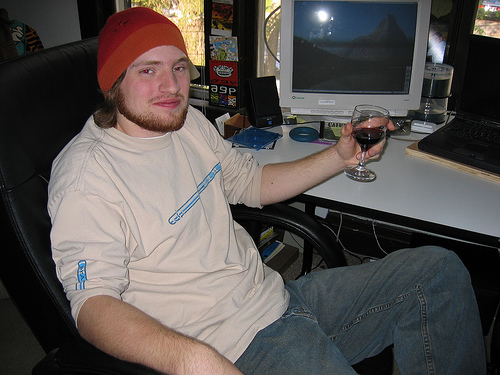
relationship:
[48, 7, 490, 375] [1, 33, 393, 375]
man sitting in chair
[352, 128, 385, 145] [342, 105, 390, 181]
wine in wine glass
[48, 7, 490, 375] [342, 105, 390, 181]
man holding wine glass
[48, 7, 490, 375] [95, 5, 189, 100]
man wearing hat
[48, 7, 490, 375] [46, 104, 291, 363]
man wearing shirt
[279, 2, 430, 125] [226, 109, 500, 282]
computer monitor on table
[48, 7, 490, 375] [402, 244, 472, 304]
man has knee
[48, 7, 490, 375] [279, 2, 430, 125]
man sitting next to computer monitor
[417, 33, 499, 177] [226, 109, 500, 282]
laptop computer on table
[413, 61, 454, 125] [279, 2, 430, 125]
stack of cds behind computer monitor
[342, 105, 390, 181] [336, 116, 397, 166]
wine glass in hand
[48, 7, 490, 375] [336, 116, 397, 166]
man has hand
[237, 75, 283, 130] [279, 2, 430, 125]
speaker next to computer monitor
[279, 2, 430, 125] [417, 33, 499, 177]
computer monitor next to laptop computer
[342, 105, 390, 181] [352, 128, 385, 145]
wine glass has wine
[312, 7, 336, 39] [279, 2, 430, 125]
reflection in computer monitor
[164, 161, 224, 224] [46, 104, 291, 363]
design on shirt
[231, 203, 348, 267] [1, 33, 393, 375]
arm rest on chair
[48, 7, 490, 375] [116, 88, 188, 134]
man has facial hair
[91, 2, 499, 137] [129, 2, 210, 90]
wall has window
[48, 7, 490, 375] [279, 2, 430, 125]
man sitting in front of computer monitor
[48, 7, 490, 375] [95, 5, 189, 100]
man has hat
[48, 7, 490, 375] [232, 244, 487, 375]
man wearing jeans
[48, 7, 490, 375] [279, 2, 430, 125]
man sitting by computer monitor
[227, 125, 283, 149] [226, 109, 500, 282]
cd case on table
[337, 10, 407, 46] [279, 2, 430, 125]
mountain reflection on computer monitor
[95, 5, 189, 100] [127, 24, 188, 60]
hat covers forehead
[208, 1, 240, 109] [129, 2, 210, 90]
stickers by window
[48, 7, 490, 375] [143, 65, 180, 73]
man has photo red eye